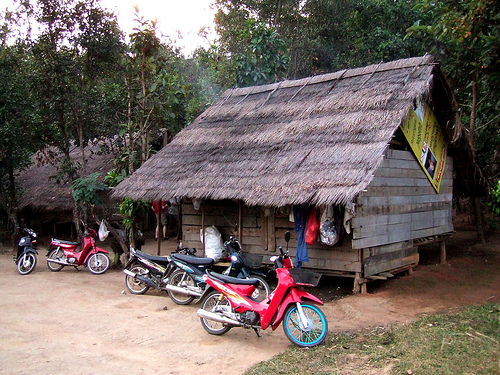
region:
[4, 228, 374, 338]
Five scooters parked outside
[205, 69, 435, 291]
A shack with a thatch roof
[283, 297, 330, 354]
The tire on the front of a scooter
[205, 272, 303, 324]
This scooter is red and white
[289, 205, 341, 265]
Dirty laundry hanging from the porch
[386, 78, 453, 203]
A metal sign being used as part of the structure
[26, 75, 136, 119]
The trees are lush and green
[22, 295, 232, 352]
There is no grass growing here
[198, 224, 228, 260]
Another bag of laundry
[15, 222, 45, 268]
that is a motorbike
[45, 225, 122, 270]
that is a motorbike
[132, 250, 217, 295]
that is a motorbike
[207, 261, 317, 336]
that is a motorbike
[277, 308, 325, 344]
that is a wheel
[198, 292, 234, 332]
that is a wheel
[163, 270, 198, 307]
that is a wheel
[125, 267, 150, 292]
that is a wheel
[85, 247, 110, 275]
that is a wheel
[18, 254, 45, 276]
that is a wheel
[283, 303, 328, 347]
Front tire with light blue rim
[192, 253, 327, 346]
Red motor scooter on dirt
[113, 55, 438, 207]
Thatched roof on building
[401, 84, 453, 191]
Yellow sign on wall of house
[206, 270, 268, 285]
Black seat on motor scooter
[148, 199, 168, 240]
Man wearing shorts beside building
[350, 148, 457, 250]
Light brown wooden wall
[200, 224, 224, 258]
White garbage bag on porch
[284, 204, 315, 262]
Clothing hanging on porch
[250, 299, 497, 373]
Patch of grass beside building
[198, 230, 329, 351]
red motorbike near building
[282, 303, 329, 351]
blue and black tire on red bike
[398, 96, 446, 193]
yellow sign on side of building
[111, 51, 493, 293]
small old wooden building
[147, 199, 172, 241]
man in red shirt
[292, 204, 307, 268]
blue jeans hanging on front of building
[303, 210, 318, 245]
red bag hanging on building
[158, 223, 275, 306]
black motorbike behind red bike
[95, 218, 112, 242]
plastic bag hanging from tree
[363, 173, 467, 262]
The building is made of wood.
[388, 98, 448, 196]
The sign is yellow.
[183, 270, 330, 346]
The bike is red.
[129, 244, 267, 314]
The bikes are black.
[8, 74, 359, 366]
The bikes are next to the house.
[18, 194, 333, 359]
The bikes are parked.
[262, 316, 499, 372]
The grass is dying.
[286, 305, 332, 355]
The tire is blue.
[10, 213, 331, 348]
several motorbikes parked in front of shack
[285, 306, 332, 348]
tire with teal paint on side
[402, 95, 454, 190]
large sign on side of shack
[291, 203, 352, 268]
clothes hanging beneath straw roof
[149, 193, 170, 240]
person in a red shirt and khaki shorts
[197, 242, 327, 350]
red bike with basket on front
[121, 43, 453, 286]
a house on a street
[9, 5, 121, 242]
a tree in a field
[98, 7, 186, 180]
a tree in a field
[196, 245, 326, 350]
a two wheeled motor bike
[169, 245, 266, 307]
a two wheeled motor bike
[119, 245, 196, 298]
a two wheeled motor bike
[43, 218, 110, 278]
a two wheeled motor bike